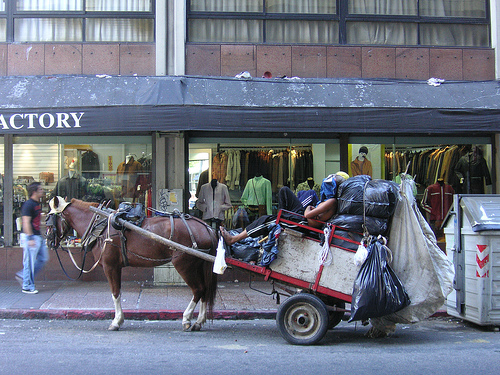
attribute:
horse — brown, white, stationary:
[37, 194, 228, 330]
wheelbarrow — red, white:
[217, 162, 416, 338]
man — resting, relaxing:
[214, 175, 340, 246]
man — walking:
[19, 176, 60, 302]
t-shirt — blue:
[20, 196, 45, 236]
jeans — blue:
[17, 231, 51, 289]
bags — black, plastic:
[336, 180, 410, 319]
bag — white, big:
[391, 183, 456, 329]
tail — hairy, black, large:
[202, 262, 214, 308]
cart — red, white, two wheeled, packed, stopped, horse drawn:
[194, 207, 394, 319]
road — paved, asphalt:
[4, 315, 499, 374]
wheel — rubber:
[270, 291, 337, 349]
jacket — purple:
[199, 185, 240, 221]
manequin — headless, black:
[191, 173, 234, 225]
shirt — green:
[238, 176, 275, 216]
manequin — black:
[236, 169, 278, 221]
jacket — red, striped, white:
[423, 183, 456, 220]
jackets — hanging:
[209, 144, 312, 193]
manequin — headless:
[424, 177, 462, 234]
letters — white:
[57, 112, 87, 129]